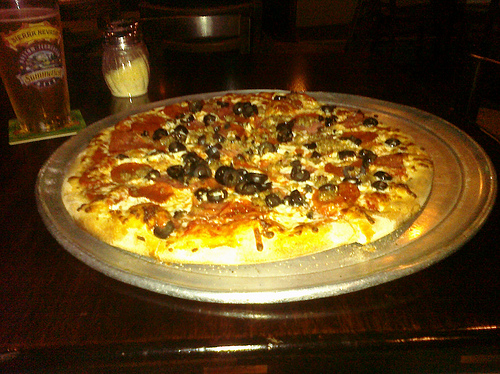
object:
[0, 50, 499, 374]
table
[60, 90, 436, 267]
pizza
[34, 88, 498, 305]
tray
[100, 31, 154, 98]
jar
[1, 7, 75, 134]
beer